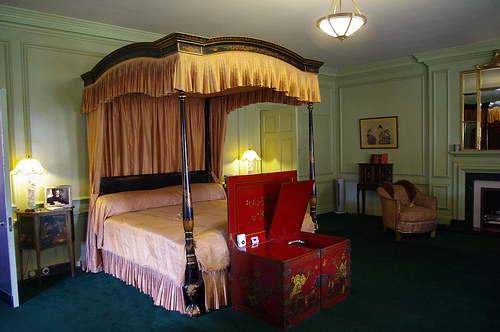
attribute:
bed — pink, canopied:
[86, 179, 314, 307]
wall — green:
[317, 37, 494, 225]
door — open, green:
[258, 112, 297, 174]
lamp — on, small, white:
[15, 157, 45, 208]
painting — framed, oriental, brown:
[358, 120, 399, 149]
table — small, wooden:
[19, 210, 76, 280]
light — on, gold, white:
[317, 19, 364, 41]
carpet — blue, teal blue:
[1, 215, 497, 327]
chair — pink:
[379, 179, 442, 239]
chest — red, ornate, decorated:
[223, 164, 359, 322]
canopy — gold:
[89, 31, 317, 120]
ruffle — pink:
[90, 60, 320, 113]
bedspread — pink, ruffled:
[101, 198, 235, 275]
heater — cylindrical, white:
[334, 177, 345, 213]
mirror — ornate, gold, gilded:
[458, 53, 499, 157]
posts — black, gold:
[179, 94, 202, 315]